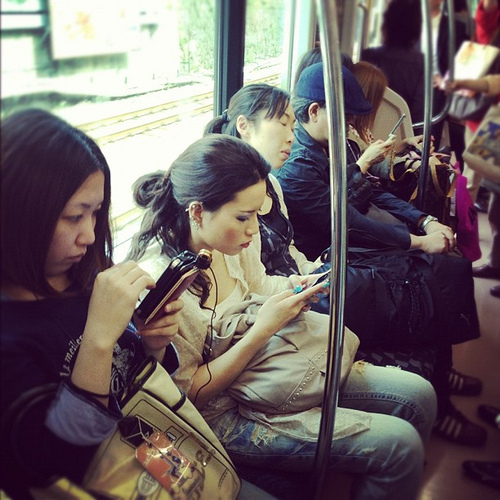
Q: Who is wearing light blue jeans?
A: Young woman.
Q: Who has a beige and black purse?
A: The woman on the left.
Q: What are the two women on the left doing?
A: Looking at their phones.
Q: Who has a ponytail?
A: Two Asian women.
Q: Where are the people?
A: On the train.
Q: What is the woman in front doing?
A: Looking at her cell phone.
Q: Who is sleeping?
A: The third woman.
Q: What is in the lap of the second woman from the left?
A: A purse.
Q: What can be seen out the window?
A: Train tracks.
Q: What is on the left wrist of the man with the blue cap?
A: A watch.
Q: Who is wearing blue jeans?
A: The second girl from the left.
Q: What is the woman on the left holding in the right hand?
A: A cell phone.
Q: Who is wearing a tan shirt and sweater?
A: The second woman from the left.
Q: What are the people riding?
A: Train.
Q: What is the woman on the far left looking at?
A: Cellphone.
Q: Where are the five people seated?
A: A train.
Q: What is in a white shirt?
A: The woman.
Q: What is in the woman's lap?
A: The grey bag.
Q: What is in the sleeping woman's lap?
A: The black bag.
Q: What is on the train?
A: The metal pole.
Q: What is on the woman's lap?
A: The black and tan bag.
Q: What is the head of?
A: The sleeping woman.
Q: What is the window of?
A: The train.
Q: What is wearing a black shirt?
A: The woman.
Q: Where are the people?
A: The train.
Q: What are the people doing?
A: Sitting.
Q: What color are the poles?
A: Silver.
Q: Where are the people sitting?
A: On seats.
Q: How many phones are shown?
A: Three.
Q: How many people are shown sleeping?
A: One.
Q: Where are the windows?
A: Behind people.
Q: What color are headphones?
A: Black.